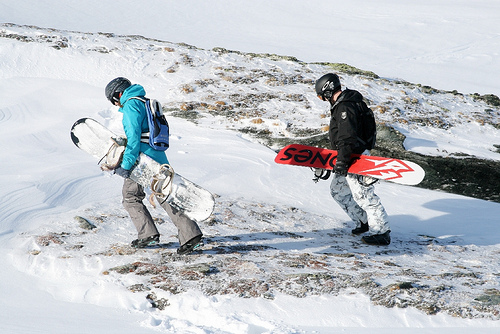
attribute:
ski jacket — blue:
[101, 64, 179, 189]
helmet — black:
[300, 46, 361, 126]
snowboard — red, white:
[287, 128, 447, 206]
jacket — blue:
[120, 85, 169, 167]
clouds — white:
[407, 20, 483, 63]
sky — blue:
[2, 1, 499, 97]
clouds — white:
[363, 25, 468, 78]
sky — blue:
[38, 0, 476, 172]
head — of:
[314, 72, 339, 104]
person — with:
[265, 54, 407, 256]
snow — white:
[2, 21, 484, 331]